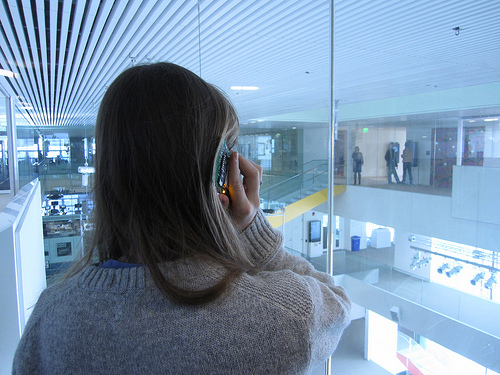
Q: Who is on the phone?
A: Lady.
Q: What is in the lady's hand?
A: Phone.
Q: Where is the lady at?
A: Shopping Mall.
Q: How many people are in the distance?
A: Three.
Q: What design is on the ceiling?
A: Stripes.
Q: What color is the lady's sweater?
A: Gray.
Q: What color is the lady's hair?
A: Brown.